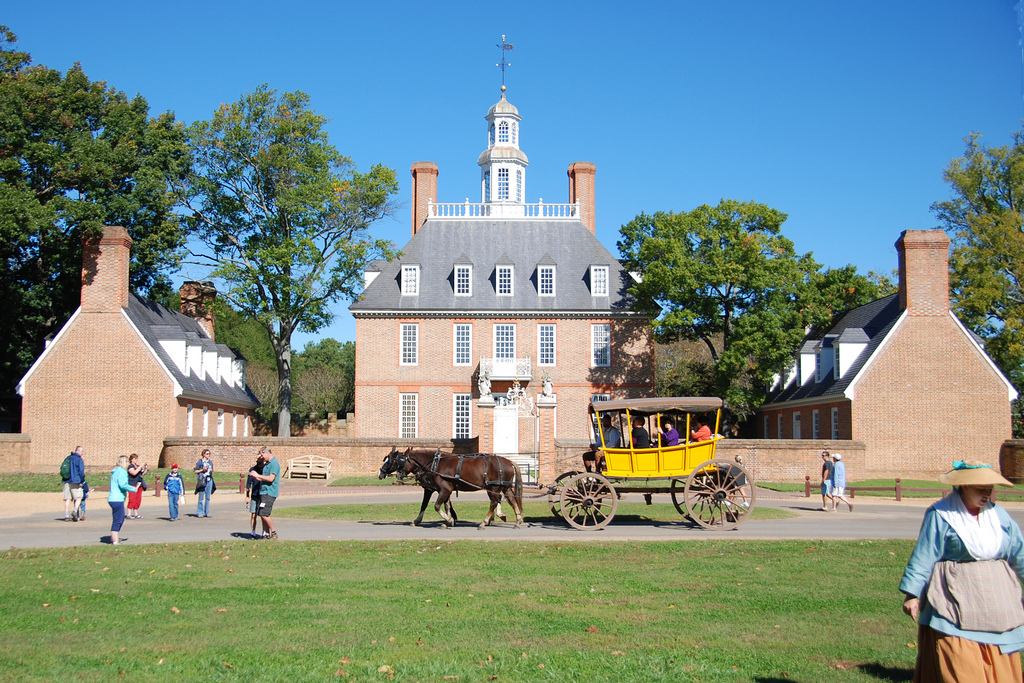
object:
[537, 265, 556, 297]
window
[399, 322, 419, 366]
window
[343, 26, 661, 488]
brick building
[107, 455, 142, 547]
people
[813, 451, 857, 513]
people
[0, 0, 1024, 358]
sky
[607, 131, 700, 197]
clouds